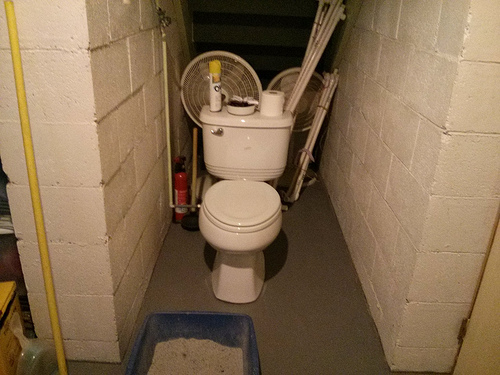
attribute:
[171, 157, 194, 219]
fire extinguisher — red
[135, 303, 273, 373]
litter box — blue, for cat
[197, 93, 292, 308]
toilet — white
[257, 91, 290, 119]
toilet paper — roll, white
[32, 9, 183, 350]
wall — white, tile, tiled, square tile, block, white tile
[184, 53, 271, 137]
fan — round, white, tall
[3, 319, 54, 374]
dust pan — transparent, clear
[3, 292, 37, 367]
box — yellow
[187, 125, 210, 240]
plunger — black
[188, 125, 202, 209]
handle — wooden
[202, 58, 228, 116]
can — air freshner, yellow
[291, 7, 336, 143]
lighbulbs — flourescent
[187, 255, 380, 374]
ground — gray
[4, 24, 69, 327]
pole — yellow